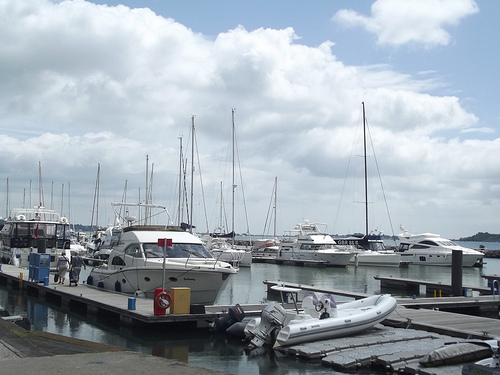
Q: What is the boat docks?
A: Wooden planked.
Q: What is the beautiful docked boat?
A: White.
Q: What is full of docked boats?
A: Small harbor.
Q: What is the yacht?
A: Docked.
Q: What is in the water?
A: Various yachts.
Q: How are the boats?
A: Several in the dock.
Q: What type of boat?
A: Yachts.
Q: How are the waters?
A: Calm.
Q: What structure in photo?
A: Bridges.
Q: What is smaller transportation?
A: Boat.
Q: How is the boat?
A: Parked.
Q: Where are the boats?
A: In marina.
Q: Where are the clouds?
A: Sky.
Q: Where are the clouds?
A: In sky.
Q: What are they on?
A: Water.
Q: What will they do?
A: Sail.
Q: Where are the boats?
A: Water.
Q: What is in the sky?
A: Clouds.